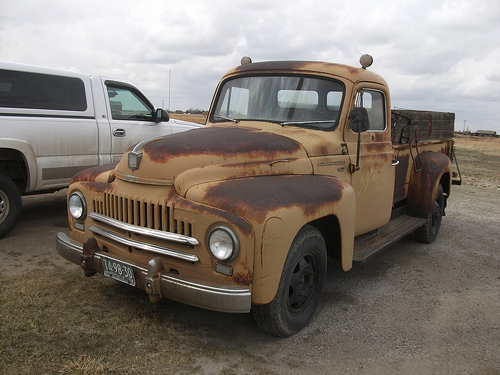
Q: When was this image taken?
A: Daytime.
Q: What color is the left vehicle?
A: White.